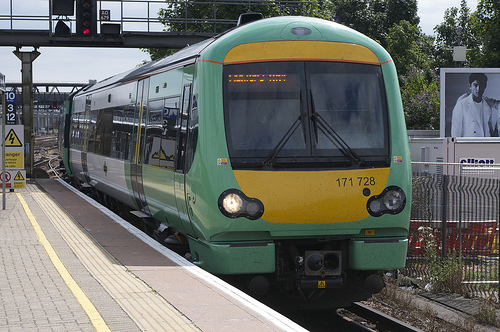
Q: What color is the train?
A: Green.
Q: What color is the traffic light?
A: Red.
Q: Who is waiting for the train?
A: No one.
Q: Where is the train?
A: On the track.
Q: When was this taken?
A: Daytime.